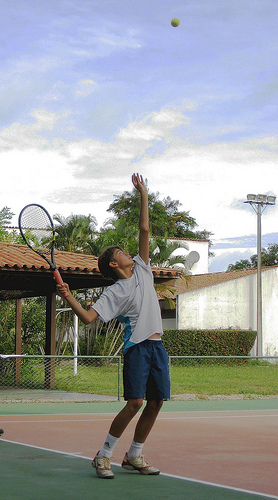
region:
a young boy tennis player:
[16, 171, 170, 479]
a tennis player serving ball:
[16, 16, 179, 476]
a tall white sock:
[97, 433, 119, 458]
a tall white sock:
[128, 439, 144, 457]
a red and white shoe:
[90, 449, 114, 477]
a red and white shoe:
[121, 451, 160, 476]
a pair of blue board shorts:
[121, 339, 170, 398]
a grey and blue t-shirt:
[91, 253, 161, 349]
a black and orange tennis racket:
[19, 203, 69, 297]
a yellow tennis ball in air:
[170, 18, 180, 27]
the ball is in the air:
[169, 15, 182, 29]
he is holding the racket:
[48, 277, 71, 295]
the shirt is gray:
[136, 292, 150, 309]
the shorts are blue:
[131, 364, 139, 378]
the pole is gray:
[254, 254, 263, 278]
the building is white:
[208, 295, 224, 309]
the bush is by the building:
[197, 325, 216, 334]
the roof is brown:
[63, 257, 75, 264]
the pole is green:
[88, 352, 107, 359]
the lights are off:
[246, 191, 274, 205]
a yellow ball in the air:
[171, 17, 179, 28]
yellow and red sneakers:
[89, 449, 159, 479]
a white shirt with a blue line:
[91, 252, 165, 351]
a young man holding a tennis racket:
[18, 203, 72, 296]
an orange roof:
[1, 242, 186, 276]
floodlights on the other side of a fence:
[245, 193, 276, 364]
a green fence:
[0, 354, 277, 401]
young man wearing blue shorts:
[123, 338, 171, 401]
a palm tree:
[40, 211, 98, 364]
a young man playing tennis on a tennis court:
[17, 172, 169, 479]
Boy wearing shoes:
[86, 446, 161, 478]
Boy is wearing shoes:
[90, 446, 162, 478]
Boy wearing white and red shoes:
[89, 445, 164, 482]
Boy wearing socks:
[98, 429, 145, 456]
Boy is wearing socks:
[96, 430, 144, 460]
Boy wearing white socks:
[96, 430, 147, 460]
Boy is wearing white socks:
[96, 430, 147, 460]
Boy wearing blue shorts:
[121, 333, 174, 401]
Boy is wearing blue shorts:
[118, 331, 174, 403]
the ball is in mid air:
[170, 16, 179, 27]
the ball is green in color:
[170, 16, 180, 27]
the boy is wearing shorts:
[121, 337, 173, 403]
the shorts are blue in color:
[120, 335, 169, 401]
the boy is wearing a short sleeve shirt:
[87, 253, 165, 347]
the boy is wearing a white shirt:
[90, 251, 167, 349]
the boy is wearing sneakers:
[90, 447, 160, 479]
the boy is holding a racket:
[18, 201, 74, 296]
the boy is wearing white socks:
[97, 431, 152, 457]